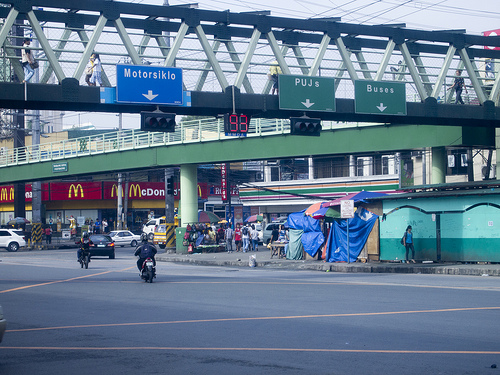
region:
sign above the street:
[113, 53, 189, 118]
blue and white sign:
[94, 54, 184, 124]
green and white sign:
[276, 71, 339, 116]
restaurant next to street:
[42, 173, 160, 223]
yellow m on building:
[62, 171, 102, 206]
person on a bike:
[128, 223, 174, 300]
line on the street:
[221, 304, 293, 362]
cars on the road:
[92, 220, 125, 264]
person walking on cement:
[393, 220, 423, 261]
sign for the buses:
[353, 56, 418, 126]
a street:
[211, 282, 301, 331]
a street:
[321, 310, 360, 367]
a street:
[311, 336, 333, 368]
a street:
[331, 265, 373, 365]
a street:
[302, 348, 338, 372]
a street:
[317, 263, 362, 337]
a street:
[294, 357, 312, 367]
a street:
[326, 288, 356, 341]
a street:
[296, 368, 304, 373]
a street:
[313, 303, 345, 354]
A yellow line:
[270, 298, 371, 349]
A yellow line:
[290, 255, 364, 373]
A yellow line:
[260, 315, 327, 373]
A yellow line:
[267, 314, 317, 348]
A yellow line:
[245, 284, 340, 374]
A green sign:
[263, 21, 356, 122]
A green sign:
[243, 35, 342, 217]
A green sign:
[272, 60, 390, 217]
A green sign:
[238, 0, 316, 162]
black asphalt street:
[0, 250, 495, 373]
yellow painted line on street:
[0, 255, 140, 291]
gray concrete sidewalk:
[155, 245, 496, 275]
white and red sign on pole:
[336, 195, 351, 215]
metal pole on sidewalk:
[340, 216, 347, 261]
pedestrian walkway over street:
[0, 0, 495, 125]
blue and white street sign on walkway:
[111, 60, 181, 105]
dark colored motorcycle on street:
[136, 245, 156, 284]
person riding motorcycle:
[135, 230, 155, 270]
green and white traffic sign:
[276, 68, 337, 116]